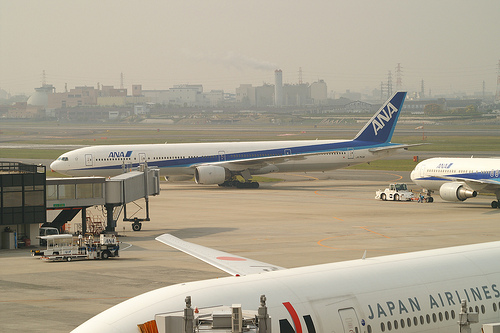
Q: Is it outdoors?
A: Yes, it is outdoors.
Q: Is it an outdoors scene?
A: Yes, it is outdoors.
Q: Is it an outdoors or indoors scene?
A: It is outdoors.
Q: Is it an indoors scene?
A: No, it is outdoors.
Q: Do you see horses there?
A: No, there are no horses.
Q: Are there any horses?
A: No, there are no horses.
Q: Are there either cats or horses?
A: No, there are no horses or cats.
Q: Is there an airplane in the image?
A: Yes, there is an airplane.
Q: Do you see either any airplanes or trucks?
A: Yes, there is an airplane.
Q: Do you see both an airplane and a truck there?
A: Yes, there are both an airplane and a truck.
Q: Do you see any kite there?
A: No, there are no kites.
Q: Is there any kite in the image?
A: No, there are no kites.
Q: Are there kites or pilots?
A: No, there are no kites or pilots.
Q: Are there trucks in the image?
A: Yes, there is a truck.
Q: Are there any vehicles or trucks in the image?
A: Yes, there is a truck.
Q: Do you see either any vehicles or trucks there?
A: Yes, there is a truck.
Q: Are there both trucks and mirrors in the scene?
A: No, there is a truck but no mirrors.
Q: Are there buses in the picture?
A: No, there are no buses.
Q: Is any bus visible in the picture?
A: No, there are no buses.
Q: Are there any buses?
A: No, there are no buses.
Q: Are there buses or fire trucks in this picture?
A: No, there are no buses or fire trucks.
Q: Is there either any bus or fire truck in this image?
A: No, there are no buses or fire trucks.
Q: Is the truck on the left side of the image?
A: Yes, the truck is on the left of the image.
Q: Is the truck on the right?
A: No, the truck is on the left of the image.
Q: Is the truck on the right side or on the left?
A: The truck is on the left of the image.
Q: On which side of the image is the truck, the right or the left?
A: The truck is on the left of the image.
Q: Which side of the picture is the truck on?
A: The truck is on the left of the image.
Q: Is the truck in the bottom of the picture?
A: Yes, the truck is in the bottom of the image.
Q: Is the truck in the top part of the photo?
A: No, the truck is in the bottom of the image.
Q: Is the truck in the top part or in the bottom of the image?
A: The truck is in the bottom of the image.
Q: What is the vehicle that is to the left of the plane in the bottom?
A: The vehicle is a truck.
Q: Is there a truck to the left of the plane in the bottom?
A: Yes, there is a truck to the left of the plane.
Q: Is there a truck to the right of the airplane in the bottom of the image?
A: No, the truck is to the left of the airplane.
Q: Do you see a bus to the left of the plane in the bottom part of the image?
A: No, there is a truck to the left of the plane.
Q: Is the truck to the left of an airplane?
A: Yes, the truck is to the left of an airplane.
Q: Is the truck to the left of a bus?
A: No, the truck is to the left of an airplane.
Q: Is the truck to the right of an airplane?
A: No, the truck is to the left of an airplane.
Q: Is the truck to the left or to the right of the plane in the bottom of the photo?
A: The truck is to the left of the airplane.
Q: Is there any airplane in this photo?
A: Yes, there is an airplane.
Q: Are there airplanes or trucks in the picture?
A: Yes, there is an airplane.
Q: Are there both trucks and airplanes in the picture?
A: Yes, there are both an airplane and a truck.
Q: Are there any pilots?
A: No, there are no pilots.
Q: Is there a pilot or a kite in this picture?
A: No, there are no pilots or kites.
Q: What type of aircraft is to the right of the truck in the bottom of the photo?
A: The aircraft is an airplane.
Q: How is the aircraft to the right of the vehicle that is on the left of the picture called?
A: The aircraft is an airplane.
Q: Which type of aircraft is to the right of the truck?
A: The aircraft is an airplane.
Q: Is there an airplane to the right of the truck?
A: Yes, there is an airplane to the right of the truck.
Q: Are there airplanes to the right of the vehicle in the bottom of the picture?
A: Yes, there is an airplane to the right of the truck.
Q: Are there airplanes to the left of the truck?
A: No, the airplane is to the right of the truck.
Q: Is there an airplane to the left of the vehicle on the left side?
A: No, the airplane is to the right of the truck.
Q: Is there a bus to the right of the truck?
A: No, there is an airplane to the right of the truck.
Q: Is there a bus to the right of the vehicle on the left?
A: No, there is an airplane to the right of the truck.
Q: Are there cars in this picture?
A: No, there are no cars.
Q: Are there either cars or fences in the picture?
A: No, there are no cars or fences.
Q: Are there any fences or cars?
A: No, there are no cars or fences.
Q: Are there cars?
A: No, there are no cars.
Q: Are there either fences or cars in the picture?
A: No, there are no cars or fences.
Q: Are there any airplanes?
A: Yes, there is an airplane.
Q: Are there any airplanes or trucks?
A: Yes, there is an airplane.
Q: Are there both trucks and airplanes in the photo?
A: Yes, there are both an airplane and a truck.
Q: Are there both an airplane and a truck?
A: Yes, there are both an airplane and a truck.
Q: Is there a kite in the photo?
A: No, there are no kites.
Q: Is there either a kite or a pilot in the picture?
A: No, there are no kites or pilots.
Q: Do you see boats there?
A: No, there are no boats.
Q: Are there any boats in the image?
A: No, there are no boats.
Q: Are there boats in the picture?
A: No, there are no boats.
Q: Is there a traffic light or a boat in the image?
A: No, there are no boats or traffic lights.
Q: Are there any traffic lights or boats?
A: No, there are no boats or traffic lights.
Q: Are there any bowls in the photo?
A: No, there are no bowls.